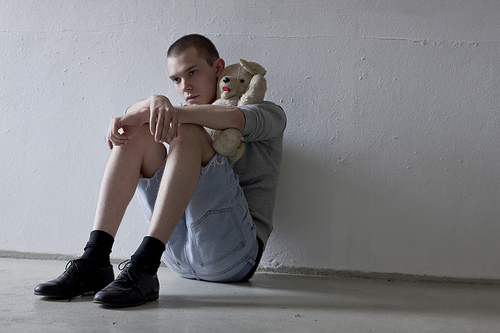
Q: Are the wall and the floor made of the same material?
A: Yes, both the wall and the floor are made of cement.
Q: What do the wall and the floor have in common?
A: The material, both the wall and the floor are concrete.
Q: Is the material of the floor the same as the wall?
A: Yes, both the floor and the wall are made of cement.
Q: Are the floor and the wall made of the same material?
A: Yes, both the floor and the wall are made of cement.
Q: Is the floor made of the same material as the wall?
A: Yes, both the floor and the wall are made of cement.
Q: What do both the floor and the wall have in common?
A: The material, both the floor and the wall are concrete.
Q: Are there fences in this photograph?
A: No, there are no fences.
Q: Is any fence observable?
A: No, there are no fences.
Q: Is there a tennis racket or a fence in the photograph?
A: No, there are no fences or rackets.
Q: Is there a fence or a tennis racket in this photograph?
A: No, there are no fences or rackets.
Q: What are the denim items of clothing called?
A: The clothing items are shorts.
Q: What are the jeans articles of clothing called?
A: The clothing items are shorts.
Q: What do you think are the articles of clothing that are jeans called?
A: The clothing items are shorts.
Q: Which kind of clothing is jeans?
A: The clothing is shorts.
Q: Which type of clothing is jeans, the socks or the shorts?
A: The shorts are jeans.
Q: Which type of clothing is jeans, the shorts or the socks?
A: The shorts are jeans.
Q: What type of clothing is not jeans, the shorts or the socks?
A: The socks are not jeans.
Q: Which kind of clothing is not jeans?
A: The clothing is socks.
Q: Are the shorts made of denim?
A: Yes, the shorts are made of denim.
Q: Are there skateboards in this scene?
A: No, there are no skateboards.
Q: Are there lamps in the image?
A: No, there are no lamps.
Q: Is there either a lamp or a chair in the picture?
A: No, there are no lamps or chairs.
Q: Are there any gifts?
A: No, there are no gifts.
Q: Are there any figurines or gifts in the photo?
A: No, there are no gifts or figurines.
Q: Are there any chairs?
A: No, there are no chairs.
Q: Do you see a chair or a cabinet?
A: No, there are no chairs or cabinets.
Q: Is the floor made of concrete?
A: Yes, the floor is made of concrete.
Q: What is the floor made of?
A: The floor is made of concrete.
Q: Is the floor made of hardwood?
A: No, the floor is made of cement.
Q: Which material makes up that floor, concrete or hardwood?
A: The floor is made of concrete.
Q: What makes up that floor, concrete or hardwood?
A: The floor is made of concrete.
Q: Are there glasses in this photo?
A: No, there are no glasses.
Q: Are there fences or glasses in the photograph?
A: No, there are no glasses or fences.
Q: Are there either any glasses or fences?
A: No, there are no glasses or fences.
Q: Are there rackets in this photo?
A: No, there are no rackets.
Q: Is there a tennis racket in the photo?
A: No, there are no rackets.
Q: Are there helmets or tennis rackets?
A: No, there are no tennis rackets or helmets.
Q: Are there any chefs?
A: No, there are no chefs.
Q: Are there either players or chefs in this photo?
A: No, there are no chefs or players.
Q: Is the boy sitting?
A: Yes, the boy is sitting.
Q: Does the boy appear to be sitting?
A: Yes, the boy is sitting.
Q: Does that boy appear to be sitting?
A: Yes, the boy is sitting.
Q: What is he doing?
A: The boy is sitting.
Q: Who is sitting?
A: The boy is sitting.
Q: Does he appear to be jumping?
A: No, the boy is sitting.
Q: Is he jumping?
A: No, the boy is sitting.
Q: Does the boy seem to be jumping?
A: No, the boy is sitting.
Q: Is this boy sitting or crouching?
A: The boy is sitting.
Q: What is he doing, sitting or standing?
A: The boy is sitting.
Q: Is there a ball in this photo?
A: No, there are no balls.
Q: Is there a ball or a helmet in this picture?
A: No, there are no balls or helmets.